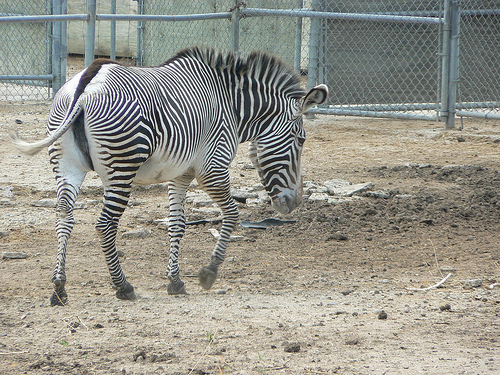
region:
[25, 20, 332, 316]
the zebra in the pen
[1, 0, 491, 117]
chain link fence of the pen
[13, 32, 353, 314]
the zebra is striped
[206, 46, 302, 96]
the mane on the zebra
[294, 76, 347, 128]
ear of the zebra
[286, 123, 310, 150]
eye of the zebra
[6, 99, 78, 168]
tail of the zebra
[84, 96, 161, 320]
hind leg of the zebra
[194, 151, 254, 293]
leg of the zebra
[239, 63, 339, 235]
head of the zebra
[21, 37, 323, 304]
a zebra in a pen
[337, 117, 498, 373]
clumps of dry dirt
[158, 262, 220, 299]
front hooves of a zebra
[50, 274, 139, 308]
rear hooves of a zebra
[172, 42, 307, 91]
a zebra's short mane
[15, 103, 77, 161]
a zebra's short tail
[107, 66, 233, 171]
black and white stripes on a zebra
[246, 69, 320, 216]
black and white head of a zebra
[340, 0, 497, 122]
cage fence with gate in it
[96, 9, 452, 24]
large gray pipe in fence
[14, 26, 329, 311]
black and white animal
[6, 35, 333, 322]
zebra that is striped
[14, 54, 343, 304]
animal with black and white stripes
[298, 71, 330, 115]
right ear of zebra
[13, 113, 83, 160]
white tail of zebra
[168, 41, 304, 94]
black and white mane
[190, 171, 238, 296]
right front leg of zebra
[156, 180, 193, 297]
left front leg of zebra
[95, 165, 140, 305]
right hind leg of zebra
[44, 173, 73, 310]
left hind leg of zebra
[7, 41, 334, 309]
zebra walking in dirt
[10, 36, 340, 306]
zebra walking with head down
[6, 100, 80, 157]
zebra tail swinging left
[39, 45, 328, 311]
black and white stripes on zebra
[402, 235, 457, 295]
white stick in dirt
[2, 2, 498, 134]
metal fence beyond zebra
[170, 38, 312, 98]
mane along zebra neck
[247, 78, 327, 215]
zebra head pointed down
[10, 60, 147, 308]
rear end of zebra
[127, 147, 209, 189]
white belly of zebra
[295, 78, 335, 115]
the ear of a zebra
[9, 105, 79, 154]
the tail of a zebra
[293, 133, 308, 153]
the eye of a zebra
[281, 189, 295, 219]
the mouth of a zebra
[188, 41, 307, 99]
the mane of a zebra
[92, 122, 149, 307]
the hind leg of a zebra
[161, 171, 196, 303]
the front leg of a zebra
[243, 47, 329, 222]
the head of a zebra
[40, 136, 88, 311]
the hind leg of a zebra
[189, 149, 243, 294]
the front leg of a zebra